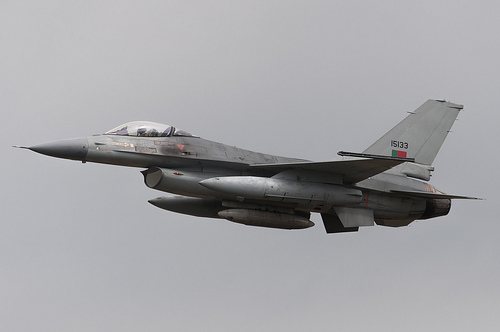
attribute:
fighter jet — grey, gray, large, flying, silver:
[11, 96, 488, 234]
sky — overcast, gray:
[0, 0, 499, 332]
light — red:
[171, 170, 181, 177]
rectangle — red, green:
[391, 147, 407, 158]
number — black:
[389, 138, 394, 149]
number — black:
[394, 139, 397, 150]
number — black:
[397, 141, 400, 149]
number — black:
[400, 140, 404, 150]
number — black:
[404, 140, 408, 152]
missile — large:
[198, 174, 365, 209]